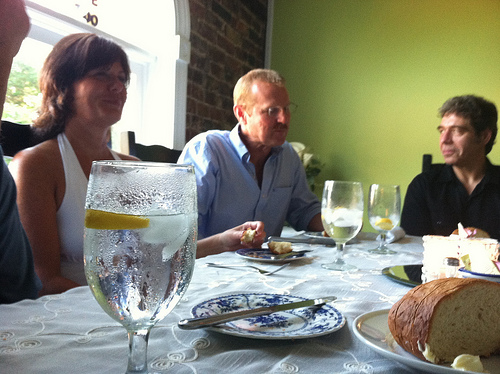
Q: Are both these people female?
A: No, they are both male and female.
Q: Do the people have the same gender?
A: No, they are both male and female.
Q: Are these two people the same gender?
A: No, they are both male and female.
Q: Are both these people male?
A: No, they are both male and female.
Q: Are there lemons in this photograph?
A: Yes, there is a lemon.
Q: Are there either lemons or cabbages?
A: Yes, there is a lemon.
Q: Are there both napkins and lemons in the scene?
A: No, there is a lemon but no napkins.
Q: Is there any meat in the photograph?
A: No, there is no meat.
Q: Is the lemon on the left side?
A: Yes, the lemon is on the left of the image.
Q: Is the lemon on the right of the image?
A: No, the lemon is on the left of the image.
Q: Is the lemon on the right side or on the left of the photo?
A: The lemon is on the left of the image.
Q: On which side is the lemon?
A: The lemon is on the left of the image.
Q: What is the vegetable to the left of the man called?
A: The vegetable is a lemon.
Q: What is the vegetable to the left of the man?
A: The vegetable is a lemon.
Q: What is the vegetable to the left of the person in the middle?
A: The vegetable is a lemon.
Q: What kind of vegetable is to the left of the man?
A: The vegetable is a lemon.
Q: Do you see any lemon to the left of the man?
A: Yes, there is a lemon to the left of the man.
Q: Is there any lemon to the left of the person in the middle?
A: Yes, there is a lemon to the left of the man.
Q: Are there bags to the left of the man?
A: No, there is a lemon to the left of the man.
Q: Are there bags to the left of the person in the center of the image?
A: No, there is a lemon to the left of the man.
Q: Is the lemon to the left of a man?
A: Yes, the lemon is to the left of a man.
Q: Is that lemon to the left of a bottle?
A: No, the lemon is to the left of a man.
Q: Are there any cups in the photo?
A: No, there are no cups.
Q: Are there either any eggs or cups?
A: No, there are no cups or eggs.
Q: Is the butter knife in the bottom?
A: Yes, the butter knife is in the bottom of the image.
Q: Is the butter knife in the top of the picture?
A: No, the butter knife is in the bottom of the image.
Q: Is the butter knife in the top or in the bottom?
A: The butter knife is in the bottom of the image.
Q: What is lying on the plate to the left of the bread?
A: The butter knife is lying on the plate.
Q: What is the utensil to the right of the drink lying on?
A: The butter knife is lying on the plate.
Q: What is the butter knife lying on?
A: The butter knife is lying on the plate.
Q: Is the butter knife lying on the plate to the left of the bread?
A: Yes, the butter knife is lying on the plate.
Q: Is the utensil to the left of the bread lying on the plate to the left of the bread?
A: Yes, the butter knife is lying on the plate.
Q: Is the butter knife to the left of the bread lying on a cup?
A: No, the butter knife is lying on the plate.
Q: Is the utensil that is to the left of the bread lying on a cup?
A: No, the butter knife is lying on the plate.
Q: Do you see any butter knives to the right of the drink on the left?
A: Yes, there is a butter knife to the right of the drink.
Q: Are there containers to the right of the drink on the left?
A: No, there is a butter knife to the right of the drink.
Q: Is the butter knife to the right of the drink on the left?
A: Yes, the butter knife is to the right of the drink.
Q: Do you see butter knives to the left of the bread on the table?
A: Yes, there is a butter knife to the left of the bread.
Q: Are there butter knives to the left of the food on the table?
A: Yes, there is a butter knife to the left of the bread.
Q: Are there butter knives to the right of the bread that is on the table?
A: No, the butter knife is to the left of the bread.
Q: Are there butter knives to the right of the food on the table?
A: No, the butter knife is to the left of the bread.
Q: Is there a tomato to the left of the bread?
A: No, there is a butter knife to the left of the bread.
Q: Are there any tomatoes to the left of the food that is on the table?
A: No, there is a butter knife to the left of the bread.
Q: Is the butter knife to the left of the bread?
A: Yes, the butter knife is to the left of the bread.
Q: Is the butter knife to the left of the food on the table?
A: Yes, the butter knife is to the left of the bread.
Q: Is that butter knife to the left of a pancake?
A: No, the butter knife is to the left of the bread.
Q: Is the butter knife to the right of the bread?
A: No, the butter knife is to the left of the bread.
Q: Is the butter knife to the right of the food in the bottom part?
A: No, the butter knife is to the left of the bread.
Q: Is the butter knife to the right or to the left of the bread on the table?
A: The butter knife is to the left of the bread.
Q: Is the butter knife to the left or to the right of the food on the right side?
A: The butter knife is to the left of the bread.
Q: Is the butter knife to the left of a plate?
A: Yes, the butter knife is to the left of a plate.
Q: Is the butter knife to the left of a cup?
A: No, the butter knife is to the left of a plate.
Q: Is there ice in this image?
A: Yes, there is ice.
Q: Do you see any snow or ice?
A: Yes, there is ice.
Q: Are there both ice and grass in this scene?
A: No, there is ice but no grass.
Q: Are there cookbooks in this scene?
A: No, there are no cookbooks.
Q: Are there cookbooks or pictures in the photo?
A: No, there are no cookbooks or pictures.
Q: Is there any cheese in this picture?
A: No, there is no cheese.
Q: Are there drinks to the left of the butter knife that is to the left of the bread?
A: Yes, there is a drink to the left of the butter knife.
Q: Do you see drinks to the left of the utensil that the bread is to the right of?
A: Yes, there is a drink to the left of the butter knife.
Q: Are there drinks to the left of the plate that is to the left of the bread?
A: Yes, there is a drink to the left of the plate.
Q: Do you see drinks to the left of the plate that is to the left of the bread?
A: Yes, there is a drink to the left of the plate.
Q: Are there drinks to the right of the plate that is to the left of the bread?
A: No, the drink is to the left of the plate.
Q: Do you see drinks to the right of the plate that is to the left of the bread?
A: No, the drink is to the left of the plate.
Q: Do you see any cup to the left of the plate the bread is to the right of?
A: No, there is a drink to the left of the plate.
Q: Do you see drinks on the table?
A: Yes, there is a drink on the table.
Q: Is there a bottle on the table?
A: No, there is a drink on the table.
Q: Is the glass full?
A: Yes, the glass is full.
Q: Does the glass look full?
A: Yes, the glass is full.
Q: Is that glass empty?
A: No, the glass is full.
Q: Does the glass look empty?
A: No, the glass is full.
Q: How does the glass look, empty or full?
A: The glass is full.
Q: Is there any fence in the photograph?
A: No, there are no fences.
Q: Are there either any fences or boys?
A: No, there are no fences or boys.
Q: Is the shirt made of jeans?
A: Yes, the shirt is made of jeans.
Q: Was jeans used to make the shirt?
A: Yes, the shirt is made of jeans.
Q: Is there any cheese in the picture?
A: No, there is no cheese.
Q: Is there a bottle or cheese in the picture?
A: No, there are no cheese or bottles.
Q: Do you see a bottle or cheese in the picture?
A: No, there are no cheese or bottles.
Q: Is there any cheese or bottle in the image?
A: No, there are no cheese or bottles.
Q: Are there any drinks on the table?
A: Yes, there is a drink on the table.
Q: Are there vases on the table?
A: No, there is a drink on the table.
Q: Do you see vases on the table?
A: No, there is a drink on the table.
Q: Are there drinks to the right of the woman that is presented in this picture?
A: Yes, there is a drink to the right of the woman.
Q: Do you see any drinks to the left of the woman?
A: No, the drink is to the right of the woman.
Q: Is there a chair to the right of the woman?
A: No, there is a drink to the right of the woman.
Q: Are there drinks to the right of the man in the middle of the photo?
A: Yes, there is a drink to the right of the man.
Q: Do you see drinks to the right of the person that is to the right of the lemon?
A: Yes, there is a drink to the right of the man.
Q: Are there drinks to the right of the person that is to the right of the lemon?
A: Yes, there is a drink to the right of the man.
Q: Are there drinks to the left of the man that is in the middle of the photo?
A: No, the drink is to the right of the man.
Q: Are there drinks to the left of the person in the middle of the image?
A: No, the drink is to the right of the man.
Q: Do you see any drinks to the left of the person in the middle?
A: No, the drink is to the right of the man.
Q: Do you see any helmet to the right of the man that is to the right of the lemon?
A: No, there is a drink to the right of the man.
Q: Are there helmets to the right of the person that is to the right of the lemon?
A: No, there is a drink to the right of the man.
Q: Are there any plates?
A: Yes, there is a plate.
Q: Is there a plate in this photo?
A: Yes, there is a plate.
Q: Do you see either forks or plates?
A: Yes, there is a plate.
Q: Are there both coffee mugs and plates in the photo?
A: No, there is a plate but no coffee mugs.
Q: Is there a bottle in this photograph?
A: No, there are no bottles.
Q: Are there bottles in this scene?
A: No, there are no bottles.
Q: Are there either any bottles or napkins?
A: No, there are no bottles or napkins.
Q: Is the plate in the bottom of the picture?
A: Yes, the plate is in the bottom of the image.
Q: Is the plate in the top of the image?
A: No, the plate is in the bottom of the image.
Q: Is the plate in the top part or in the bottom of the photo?
A: The plate is in the bottom of the image.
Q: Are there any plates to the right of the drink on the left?
A: Yes, there is a plate to the right of the drink.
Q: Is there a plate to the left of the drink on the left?
A: No, the plate is to the right of the drink.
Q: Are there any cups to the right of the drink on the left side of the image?
A: No, there is a plate to the right of the drink.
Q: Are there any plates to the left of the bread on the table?
A: Yes, there is a plate to the left of the bread.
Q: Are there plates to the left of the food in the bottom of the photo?
A: Yes, there is a plate to the left of the bread.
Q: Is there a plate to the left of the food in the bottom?
A: Yes, there is a plate to the left of the bread.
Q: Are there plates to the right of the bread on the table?
A: No, the plate is to the left of the bread.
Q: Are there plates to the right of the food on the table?
A: No, the plate is to the left of the bread.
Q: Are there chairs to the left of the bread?
A: No, there is a plate to the left of the bread.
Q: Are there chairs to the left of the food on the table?
A: No, there is a plate to the left of the bread.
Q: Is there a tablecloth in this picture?
A: Yes, there is a tablecloth.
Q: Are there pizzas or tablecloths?
A: Yes, there is a tablecloth.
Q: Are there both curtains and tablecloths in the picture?
A: No, there is a tablecloth but no curtains.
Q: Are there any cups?
A: No, there are no cups.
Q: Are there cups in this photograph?
A: No, there are no cups.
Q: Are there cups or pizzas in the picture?
A: No, there are no cups or pizzas.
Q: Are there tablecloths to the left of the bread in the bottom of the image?
A: Yes, there is a tablecloth to the left of the bread.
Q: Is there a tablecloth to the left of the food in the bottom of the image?
A: Yes, there is a tablecloth to the left of the bread.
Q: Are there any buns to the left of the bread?
A: No, there is a tablecloth to the left of the bread.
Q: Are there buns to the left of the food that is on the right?
A: No, there is a tablecloth to the left of the bread.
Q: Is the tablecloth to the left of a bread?
A: Yes, the tablecloth is to the left of a bread.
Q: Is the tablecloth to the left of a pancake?
A: No, the tablecloth is to the left of a bread.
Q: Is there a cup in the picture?
A: No, there are no cups.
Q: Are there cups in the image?
A: No, there are no cups.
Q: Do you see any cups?
A: No, there are no cups.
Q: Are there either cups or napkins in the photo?
A: No, there are no cups or napkins.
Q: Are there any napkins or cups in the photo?
A: No, there are no cups or napkins.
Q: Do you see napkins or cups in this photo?
A: No, there are no cups or napkins.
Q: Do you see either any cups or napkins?
A: No, there are no cups or napkins.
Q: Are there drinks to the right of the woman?
A: Yes, there is a drink to the right of the woman.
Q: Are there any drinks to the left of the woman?
A: No, the drink is to the right of the woman.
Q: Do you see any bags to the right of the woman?
A: No, there is a drink to the right of the woman.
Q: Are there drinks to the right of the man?
A: Yes, there is a drink to the right of the man.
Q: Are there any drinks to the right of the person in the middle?
A: Yes, there is a drink to the right of the man.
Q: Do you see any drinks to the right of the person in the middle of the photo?
A: Yes, there is a drink to the right of the man.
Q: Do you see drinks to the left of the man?
A: No, the drink is to the right of the man.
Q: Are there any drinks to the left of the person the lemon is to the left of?
A: No, the drink is to the right of the man.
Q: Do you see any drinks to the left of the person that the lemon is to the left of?
A: No, the drink is to the right of the man.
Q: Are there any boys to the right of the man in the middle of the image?
A: No, there is a drink to the right of the man.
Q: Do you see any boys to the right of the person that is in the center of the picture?
A: No, there is a drink to the right of the man.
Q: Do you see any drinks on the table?
A: Yes, there is a drink on the table.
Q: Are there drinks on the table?
A: Yes, there is a drink on the table.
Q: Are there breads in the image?
A: Yes, there is a bread.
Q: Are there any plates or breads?
A: Yes, there is a bread.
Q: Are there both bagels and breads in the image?
A: No, there is a bread but no bagels.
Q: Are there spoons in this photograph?
A: No, there are no spoons.